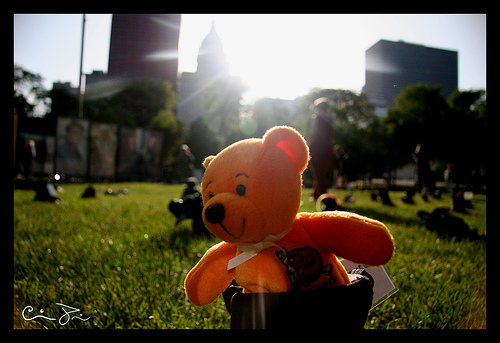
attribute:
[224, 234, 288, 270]
bow — white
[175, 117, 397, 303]
teddy bear — yellow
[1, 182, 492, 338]
field — green, grassy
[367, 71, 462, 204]
tree — leafy, green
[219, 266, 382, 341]
bucket — small, black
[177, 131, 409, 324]
teddy bear — stuffed, orange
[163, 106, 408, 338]
teddy bear — orange, small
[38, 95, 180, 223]
bill boards — large, blurry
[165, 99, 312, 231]
teddy-bear's face — orange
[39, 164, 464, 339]
field — grassy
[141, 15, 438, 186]
sunlight — bright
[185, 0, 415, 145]
rays — of sun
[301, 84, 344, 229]
person — walking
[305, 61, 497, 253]
trees — in a row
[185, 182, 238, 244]
bear nose — stuffed, black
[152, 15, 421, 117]
sky — clear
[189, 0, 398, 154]
sky — clear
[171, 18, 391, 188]
sky — clear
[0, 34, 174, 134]
sky — clear